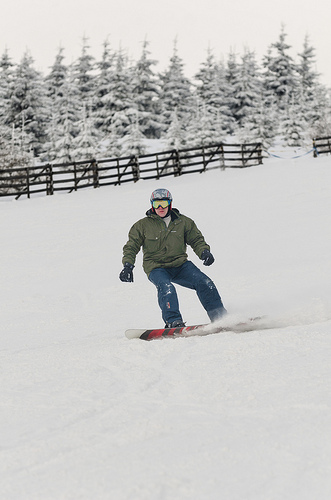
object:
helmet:
[150, 187, 173, 218]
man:
[119, 188, 228, 328]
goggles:
[152, 197, 172, 209]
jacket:
[122, 208, 211, 279]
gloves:
[202, 249, 215, 266]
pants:
[148, 260, 228, 323]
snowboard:
[125, 315, 272, 343]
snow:
[180, 451, 302, 483]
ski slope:
[0, 191, 331, 499]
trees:
[0, 23, 330, 165]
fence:
[0, 141, 265, 200]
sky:
[236, 9, 287, 14]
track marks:
[116, 347, 176, 400]